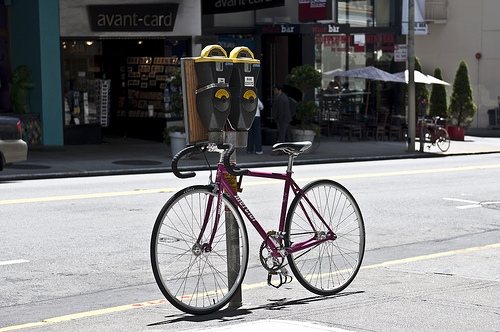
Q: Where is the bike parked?
A: Parking meters.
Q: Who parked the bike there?
A: The owner.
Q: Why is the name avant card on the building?
A: Name of business.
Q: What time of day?
A: Afternoon.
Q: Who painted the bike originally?
A: Manufacturer.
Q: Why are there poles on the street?
A: Light.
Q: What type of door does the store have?
A: The store has a sliding door.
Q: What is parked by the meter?
A: A pink bicycle.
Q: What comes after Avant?
A: Card comes after Avant.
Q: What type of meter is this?
A: A double parking meter.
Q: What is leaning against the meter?
A: A pink bike.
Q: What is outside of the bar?
A: Tables are outside.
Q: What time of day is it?
A: Daytime.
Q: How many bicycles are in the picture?
A: Two.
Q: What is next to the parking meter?
A: A bicycle.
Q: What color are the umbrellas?
A: White.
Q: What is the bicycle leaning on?
A: A parking meter.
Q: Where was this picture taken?
A: A city street.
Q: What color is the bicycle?
A: Red.